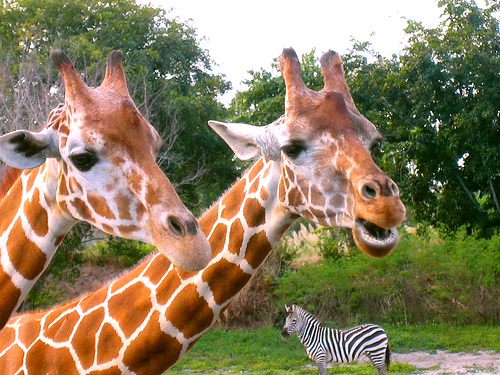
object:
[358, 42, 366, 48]
leaves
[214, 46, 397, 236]
tree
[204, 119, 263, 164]
ear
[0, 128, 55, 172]
ear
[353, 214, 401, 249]
mouth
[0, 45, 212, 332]
giraffe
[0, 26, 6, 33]
leaves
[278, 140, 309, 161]
eye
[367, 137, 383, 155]
eye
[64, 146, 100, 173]
eye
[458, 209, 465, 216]
leaves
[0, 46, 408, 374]
giraffe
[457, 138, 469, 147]
leaves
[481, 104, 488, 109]
leaves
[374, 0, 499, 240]
tree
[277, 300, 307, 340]
head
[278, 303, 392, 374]
zebra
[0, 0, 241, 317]
tree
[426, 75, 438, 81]
leaves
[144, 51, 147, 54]
leaf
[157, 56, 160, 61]
leaf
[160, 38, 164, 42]
leaf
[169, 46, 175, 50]
leaf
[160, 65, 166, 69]
leaf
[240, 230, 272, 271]
spot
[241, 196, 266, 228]
spot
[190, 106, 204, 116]
leaves